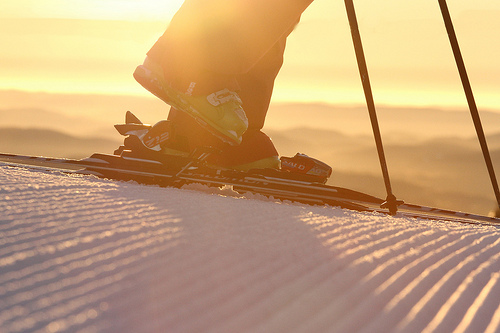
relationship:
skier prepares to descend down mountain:
[132, 0, 317, 174] [377, 222, 493, 320]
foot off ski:
[138, 41, 260, 152] [28, 147, 436, 227]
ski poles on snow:
[332, 0, 497, 227] [2, 147, 498, 329]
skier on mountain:
[126, 0, 317, 170] [0, 159, 499, 331]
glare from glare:
[107, 2, 211, 49] [108, 0, 186, 22]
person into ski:
[132, 0, 316, 172] [114, 105, 184, 188]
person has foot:
[132, 0, 314, 170] [148, 44, 242, 147]